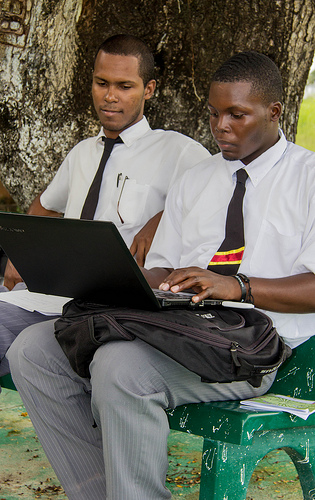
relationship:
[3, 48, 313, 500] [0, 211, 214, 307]
guy typing on computer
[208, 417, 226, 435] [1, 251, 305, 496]
spots on bench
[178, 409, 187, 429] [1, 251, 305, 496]
spots on bench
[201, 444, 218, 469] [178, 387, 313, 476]
spots on green bench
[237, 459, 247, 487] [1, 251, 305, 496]
spots on bench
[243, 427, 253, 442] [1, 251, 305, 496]
spots on bench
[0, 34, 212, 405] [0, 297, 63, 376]
guy wearing bench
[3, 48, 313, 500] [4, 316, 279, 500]
guy wearing bench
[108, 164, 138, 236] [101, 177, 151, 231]
glasses in pocket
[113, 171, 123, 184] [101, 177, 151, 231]
pen in pocket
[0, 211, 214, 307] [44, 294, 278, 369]
computer open in lap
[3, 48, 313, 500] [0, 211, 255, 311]
guy using computer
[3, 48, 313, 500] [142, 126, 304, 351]
guy wearing shirt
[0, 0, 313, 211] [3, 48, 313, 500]
tree trunk behind guy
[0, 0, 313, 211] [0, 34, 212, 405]
tree trunk behind guy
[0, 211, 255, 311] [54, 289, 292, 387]
computer sitting on backpack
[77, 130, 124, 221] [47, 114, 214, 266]
tie on shirt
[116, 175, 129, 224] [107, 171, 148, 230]
glasses in pocket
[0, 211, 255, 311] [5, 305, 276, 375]
computer in lap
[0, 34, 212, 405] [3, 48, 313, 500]
guy sitting next to guy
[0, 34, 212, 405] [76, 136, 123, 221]
guy wearing tie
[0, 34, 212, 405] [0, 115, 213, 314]
guy wearing shirt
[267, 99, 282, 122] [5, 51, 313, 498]
left ear on guy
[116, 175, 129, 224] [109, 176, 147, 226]
glasses in pocket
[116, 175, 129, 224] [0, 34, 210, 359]
glasses on guy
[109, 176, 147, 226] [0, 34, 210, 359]
pocket on guy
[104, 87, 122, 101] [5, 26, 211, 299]
nose on guy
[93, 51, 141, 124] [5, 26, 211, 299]
face on guy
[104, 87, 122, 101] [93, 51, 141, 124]
nose on face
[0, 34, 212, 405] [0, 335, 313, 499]
guy sitting on bench